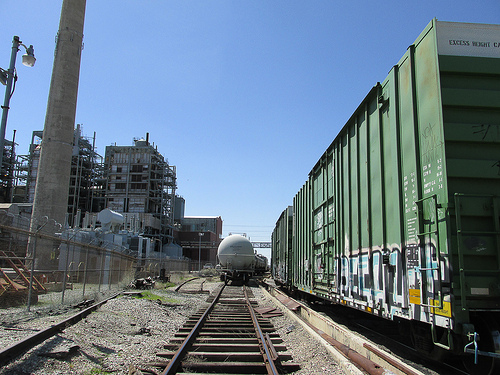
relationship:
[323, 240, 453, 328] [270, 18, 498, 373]
art on side of cars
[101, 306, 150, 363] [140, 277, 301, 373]
gravel under and around railroad tracks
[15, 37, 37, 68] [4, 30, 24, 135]
street light on pole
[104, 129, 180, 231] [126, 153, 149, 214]
building with stories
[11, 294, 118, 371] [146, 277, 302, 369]
pipes along train tracks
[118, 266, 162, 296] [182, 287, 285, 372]
building supplies for tracks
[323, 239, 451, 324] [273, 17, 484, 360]
art on side of train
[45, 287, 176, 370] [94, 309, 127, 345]
patch of gravel